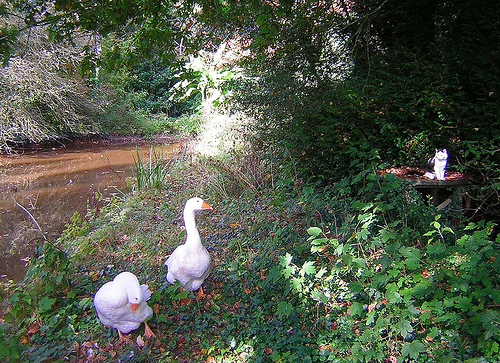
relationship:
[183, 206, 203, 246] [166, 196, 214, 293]
neck on goose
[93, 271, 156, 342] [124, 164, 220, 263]
ducks on ground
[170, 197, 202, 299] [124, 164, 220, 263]
goose on ground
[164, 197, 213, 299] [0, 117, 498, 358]
bird in garden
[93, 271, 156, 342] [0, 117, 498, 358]
ducks in garden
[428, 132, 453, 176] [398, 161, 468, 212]
cat on a bird bath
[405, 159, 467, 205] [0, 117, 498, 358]
bird bath on a garden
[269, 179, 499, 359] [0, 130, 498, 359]
foliage on a ground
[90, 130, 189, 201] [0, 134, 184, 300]
grass by river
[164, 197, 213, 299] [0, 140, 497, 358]
bird in grass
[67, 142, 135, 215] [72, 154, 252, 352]
water behind ducks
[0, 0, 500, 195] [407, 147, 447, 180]
tree behind cat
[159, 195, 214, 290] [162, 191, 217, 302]
feathers on bird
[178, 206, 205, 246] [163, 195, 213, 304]
neck on goose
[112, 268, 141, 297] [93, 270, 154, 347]
neck on goose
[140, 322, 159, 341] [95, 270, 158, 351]
foot on goose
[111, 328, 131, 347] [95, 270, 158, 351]
foot on goose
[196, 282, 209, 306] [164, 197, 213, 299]
foot on bird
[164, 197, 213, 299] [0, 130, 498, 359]
bird on ground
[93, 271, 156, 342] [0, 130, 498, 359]
ducks on ground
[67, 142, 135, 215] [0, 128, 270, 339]
water in pond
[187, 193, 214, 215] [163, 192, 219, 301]
head of duck